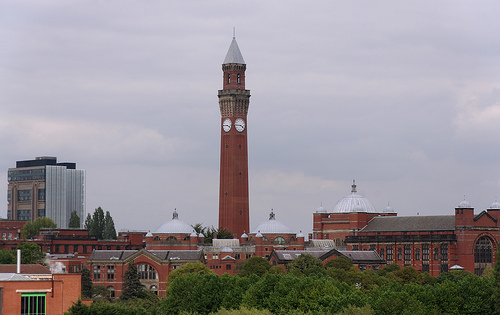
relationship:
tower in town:
[208, 20, 266, 233] [3, 137, 498, 314]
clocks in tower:
[220, 113, 249, 134] [201, 24, 265, 234]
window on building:
[29, 170, 59, 188] [15, 150, 116, 225]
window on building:
[111, 267, 127, 280] [81, 249, 165, 293]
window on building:
[88, 265, 104, 283] [339, 196, 499, 288]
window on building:
[469, 234, 495, 278] [467, 230, 484, 270]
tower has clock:
[216, 26, 251, 239] [234, 118, 246, 133]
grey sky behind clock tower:
[1, 0, 499, 240] [217, 26, 251, 245]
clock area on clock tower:
[218, 115, 250, 137] [216, 28, 254, 242]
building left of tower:
[6, 155, 87, 231] [204, 10, 271, 270]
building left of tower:
[4, 155, 85, 240] [216, 23, 251, 233]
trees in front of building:
[72, 258, 499, 313] [88, 244, 205, 299]